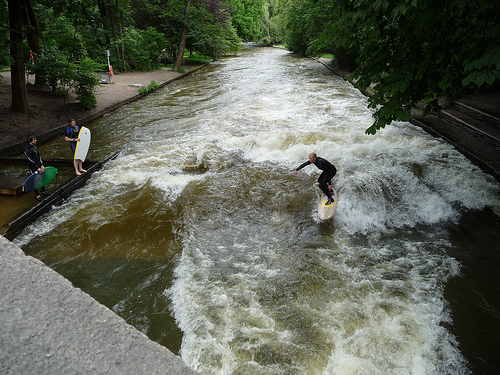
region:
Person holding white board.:
[70, 120, 130, 208]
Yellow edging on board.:
[69, 132, 89, 156]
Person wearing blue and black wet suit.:
[53, 127, 130, 194]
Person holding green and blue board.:
[16, 143, 92, 230]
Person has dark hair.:
[13, 120, 75, 187]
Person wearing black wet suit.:
[18, 137, 95, 258]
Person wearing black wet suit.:
[296, 157, 367, 231]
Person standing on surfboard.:
[301, 190, 368, 267]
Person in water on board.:
[286, 165, 366, 276]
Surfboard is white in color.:
[296, 175, 358, 274]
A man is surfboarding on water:
[273, 137, 344, 229]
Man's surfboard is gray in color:
[301, 181, 346, 226]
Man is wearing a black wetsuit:
[285, 145, 336, 200]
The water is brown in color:
[86, 197, 209, 305]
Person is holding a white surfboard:
[68, 121, 93, 166]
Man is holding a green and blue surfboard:
[15, 160, 60, 196]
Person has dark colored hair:
[16, 126, 43, 146]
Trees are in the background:
[5, 0, 495, 80]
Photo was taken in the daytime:
[6, 11, 496, 356]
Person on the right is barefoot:
[67, 160, 89, 185]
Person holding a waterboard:
[64, 113, 91, 177]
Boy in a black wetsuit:
[22, 132, 49, 204]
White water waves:
[338, 136, 440, 228]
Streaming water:
[213, 59, 332, 124]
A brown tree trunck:
[174, 30, 186, 68]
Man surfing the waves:
[293, 152, 340, 222]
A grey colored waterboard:
[74, 125, 91, 161]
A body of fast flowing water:
[221, 51, 321, 150]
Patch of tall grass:
[137, 78, 159, 93]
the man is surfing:
[280, 112, 395, 293]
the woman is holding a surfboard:
[45, 105, 109, 205]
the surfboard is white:
[60, 118, 112, 202]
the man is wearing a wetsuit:
[279, 148, 371, 240]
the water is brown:
[208, 82, 308, 362]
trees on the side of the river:
[44, 12, 339, 156]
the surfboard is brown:
[308, 177, 361, 247]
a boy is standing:
[2, 104, 68, 232]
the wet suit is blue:
[54, 119, 105, 167]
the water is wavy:
[147, 77, 349, 294]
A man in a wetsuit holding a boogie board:
[62, 119, 92, 175]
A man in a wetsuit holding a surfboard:
[19, 135, 59, 199]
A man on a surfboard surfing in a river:
[289, 152, 336, 224]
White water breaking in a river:
[10, 116, 497, 239]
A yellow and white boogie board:
[72, 125, 89, 161]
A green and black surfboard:
[23, 167, 58, 189]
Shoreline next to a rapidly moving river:
[0, 23, 214, 151]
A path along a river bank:
[238, 40, 498, 176]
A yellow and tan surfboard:
[316, 185, 336, 222]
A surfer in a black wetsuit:
[291, 152, 337, 204]